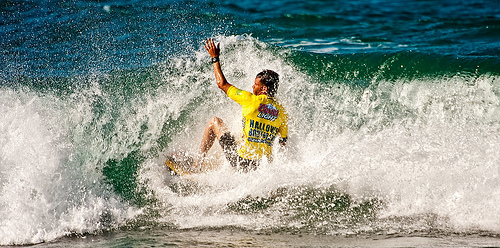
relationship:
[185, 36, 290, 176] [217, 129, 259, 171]
man wearing shorts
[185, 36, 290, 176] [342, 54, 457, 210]
man in water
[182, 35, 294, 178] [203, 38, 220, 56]
man has hand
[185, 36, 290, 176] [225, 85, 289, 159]
man wearing shirt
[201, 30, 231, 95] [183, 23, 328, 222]
arm of person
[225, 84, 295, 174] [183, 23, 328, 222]
shirt of person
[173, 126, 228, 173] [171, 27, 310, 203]
leg of person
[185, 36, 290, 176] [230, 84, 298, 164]
man in shirt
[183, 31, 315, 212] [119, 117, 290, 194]
person riding surfboard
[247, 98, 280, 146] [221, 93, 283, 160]
writing on shirt